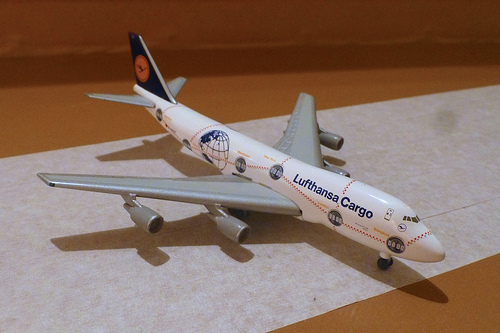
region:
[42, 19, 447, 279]
the model plane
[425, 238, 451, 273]
the nose of the plane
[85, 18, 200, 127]
the tail of the plane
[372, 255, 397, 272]
the forward landing gear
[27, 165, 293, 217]
the wing of the plane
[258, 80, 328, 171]
the wing of the plane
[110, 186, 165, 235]
the engine of the plane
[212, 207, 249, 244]
the engine of the plane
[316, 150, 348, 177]
the engine of the plane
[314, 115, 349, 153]
the engine of the plane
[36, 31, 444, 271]
Model airplane on shelf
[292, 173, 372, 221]
"Lufthansa Cargo" on model airplane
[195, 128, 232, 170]
Globe on model airplane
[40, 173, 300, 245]
Wing on model airplane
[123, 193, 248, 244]
Engines on model airplane wing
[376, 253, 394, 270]
Wheel on model airplane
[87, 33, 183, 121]
Tail of model airplane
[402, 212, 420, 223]
Windows on model airplane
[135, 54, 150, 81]
Orange decal on tail of model airplane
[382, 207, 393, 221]
Decal of door on model airplane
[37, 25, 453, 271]
little model airplane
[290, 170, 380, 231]
business name on model airplane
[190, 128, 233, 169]
globe picture on model airplane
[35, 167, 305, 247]
wing of model airplane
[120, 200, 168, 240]
jet engine on model airplane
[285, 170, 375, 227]
Lufthansa name on model airplane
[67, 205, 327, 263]
shadow of model airplane on surface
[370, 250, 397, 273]
wheels of model airplane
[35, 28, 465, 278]
white and gray model airplane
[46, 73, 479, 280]
model airplane on brown and white surface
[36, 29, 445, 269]
a model jet displayed on a table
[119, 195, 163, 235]
the jet turbine engine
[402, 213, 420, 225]
the cockpit front windshield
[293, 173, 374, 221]
the brand name logo on the fuselage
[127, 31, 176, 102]
the jets tail section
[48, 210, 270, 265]
a shadow of the jet on the floor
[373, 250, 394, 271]
the jets front landing gear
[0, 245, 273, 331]
a textured paper tarmac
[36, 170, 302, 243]
a toy jets wing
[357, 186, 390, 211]
a reflection of light on the fuselage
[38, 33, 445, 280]
white and grey plane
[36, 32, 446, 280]
model of airplane on table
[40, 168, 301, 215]
grey wing on plane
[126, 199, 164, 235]
booster jet on plane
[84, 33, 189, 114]
tail on rear of plane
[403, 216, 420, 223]
wind shield on plane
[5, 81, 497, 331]
white runner on table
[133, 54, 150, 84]
orange decal on plane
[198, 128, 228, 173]
world decal on plane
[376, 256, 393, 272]
black tire on plane